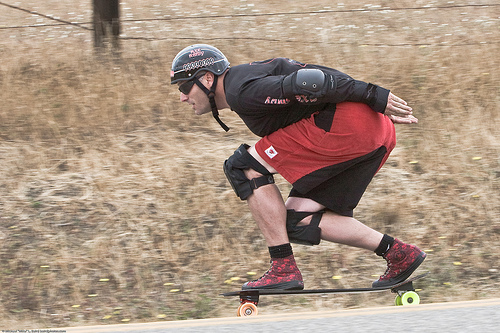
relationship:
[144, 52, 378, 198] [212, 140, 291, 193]
skateboarder has kneepads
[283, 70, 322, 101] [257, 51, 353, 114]
pads on elbow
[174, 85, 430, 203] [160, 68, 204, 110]
man has face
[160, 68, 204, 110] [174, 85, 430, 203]
sunglasses on man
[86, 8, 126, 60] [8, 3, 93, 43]
post has wires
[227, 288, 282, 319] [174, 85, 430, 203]
skateboard under man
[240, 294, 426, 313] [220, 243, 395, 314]
wheels on board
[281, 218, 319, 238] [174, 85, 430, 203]
pad on man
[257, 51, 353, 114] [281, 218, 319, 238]
elbow has pad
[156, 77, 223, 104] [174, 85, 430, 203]
glasses on man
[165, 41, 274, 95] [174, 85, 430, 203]
helmet on man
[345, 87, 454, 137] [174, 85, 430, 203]
hands of man